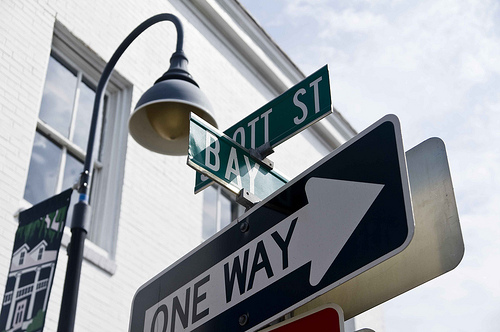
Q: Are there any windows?
A: Yes, there is a window.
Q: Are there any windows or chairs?
A: Yes, there is a window.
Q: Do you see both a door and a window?
A: No, there is a window but no doors.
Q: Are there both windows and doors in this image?
A: No, there is a window but no doors.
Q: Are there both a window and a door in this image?
A: No, there is a window but no doors.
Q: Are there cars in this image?
A: No, there are no cars.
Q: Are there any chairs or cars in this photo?
A: No, there are no cars or chairs.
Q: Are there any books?
A: No, there are no books.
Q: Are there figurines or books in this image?
A: No, there are no books or figurines.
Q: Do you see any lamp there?
A: Yes, there is a lamp.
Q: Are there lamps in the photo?
A: Yes, there is a lamp.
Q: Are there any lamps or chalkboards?
A: Yes, there is a lamp.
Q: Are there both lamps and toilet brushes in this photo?
A: No, there is a lamp but no toilet brushes.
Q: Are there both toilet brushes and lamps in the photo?
A: No, there is a lamp but no toilet brushes.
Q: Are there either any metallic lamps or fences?
A: Yes, there is a metal lamp.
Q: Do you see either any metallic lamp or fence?
A: Yes, there is a metal lamp.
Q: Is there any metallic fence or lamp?
A: Yes, there is a metal lamp.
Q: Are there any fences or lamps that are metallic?
A: Yes, the lamp is metallic.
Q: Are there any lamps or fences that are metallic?
A: Yes, the lamp is metallic.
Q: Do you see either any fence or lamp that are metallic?
A: Yes, the lamp is metallic.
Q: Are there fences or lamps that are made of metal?
A: Yes, the lamp is made of metal.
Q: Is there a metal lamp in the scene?
A: Yes, there is a metal lamp.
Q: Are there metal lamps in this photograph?
A: Yes, there is a metal lamp.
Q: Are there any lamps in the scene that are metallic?
A: Yes, there is a lamp that is metallic.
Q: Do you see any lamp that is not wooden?
A: Yes, there is a metallic lamp.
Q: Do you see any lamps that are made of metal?
A: Yes, there is a lamp that is made of metal.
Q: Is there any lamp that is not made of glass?
A: Yes, there is a lamp that is made of metal.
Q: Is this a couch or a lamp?
A: This is a lamp.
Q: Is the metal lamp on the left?
A: Yes, the lamp is on the left of the image.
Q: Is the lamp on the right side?
A: No, the lamp is on the left of the image.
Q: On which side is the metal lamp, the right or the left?
A: The lamp is on the left of the image.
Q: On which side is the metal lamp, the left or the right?
A: The lamp is on the left of the image.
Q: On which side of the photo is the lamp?
A: The lamp is on the left of the image.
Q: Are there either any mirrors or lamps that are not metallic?
A: No, there is a lamp but it is metallic.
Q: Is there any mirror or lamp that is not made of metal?
A: No, there is a lamp but it is made of metal.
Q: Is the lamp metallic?
A: Yes, the lamp is metallic.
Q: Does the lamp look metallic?
A: Yes, the lamp is metallic.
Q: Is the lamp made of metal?
A: Yes, the lamp is made of metal.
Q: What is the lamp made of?
A: The lamp is made of metal.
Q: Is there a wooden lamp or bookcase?
A: No, there is a lamp but it is metallic.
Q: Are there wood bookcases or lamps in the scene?
A: No, there is a lamp but it is metallic.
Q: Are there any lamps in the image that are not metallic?
A: No, there is a lamp but it is metallic.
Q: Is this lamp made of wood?
A: No, the lamp is made of metal.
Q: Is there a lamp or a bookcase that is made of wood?
A: No, there is a lamp but it is made of metal.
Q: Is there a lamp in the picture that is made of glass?
A: No, there is a lamp but it is made of metal.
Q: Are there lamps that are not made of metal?
A: No, there is a lamp but it is made of metal.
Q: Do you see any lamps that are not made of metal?
A: No, there is a lamp but it is made of metal.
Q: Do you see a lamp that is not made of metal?
A: No, there is a lamp but it is made of metal.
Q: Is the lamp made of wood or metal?
A: The lamp is made of metal.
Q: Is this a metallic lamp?
A: Yes, this is a metallic lamp.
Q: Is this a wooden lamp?
A: No, this is a metallic lamp.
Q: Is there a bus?
A: No, there are no buses.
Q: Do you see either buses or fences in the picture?
A: No, there are no buses or fences.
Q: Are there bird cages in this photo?
A: No, there are no bird cages.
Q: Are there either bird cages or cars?
A: No, there are no bird cages or cars.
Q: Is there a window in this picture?
A: Yes, there is a window.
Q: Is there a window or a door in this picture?
A: Yes, there is a window.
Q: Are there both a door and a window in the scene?
A: No, there is a window but no doors.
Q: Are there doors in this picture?
A: No, there are no doors.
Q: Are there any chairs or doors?
A: No, there are no doors or chairs.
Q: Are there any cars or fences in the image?
A: No, there are no cars or fences.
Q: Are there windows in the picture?
A: Yes, there is a window.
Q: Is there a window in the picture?
A: Yes, there is a window.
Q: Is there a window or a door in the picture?
A: Yes, there is a window.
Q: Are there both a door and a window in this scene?
A: No, there is a window but no doors.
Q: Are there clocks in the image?
A: No, there are no clocks.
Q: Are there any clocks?
A: No, there are no clocks.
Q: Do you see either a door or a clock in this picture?
A: No, there are no clocks or doors.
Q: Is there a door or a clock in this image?
A: No, there are no clocks or doors.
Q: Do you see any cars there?
A: No, there are no cars.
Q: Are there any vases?
A: No, there are no vases.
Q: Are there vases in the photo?
A: No, there are no vases.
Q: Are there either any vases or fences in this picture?
A: No, there are no vases or fences.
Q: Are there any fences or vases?
A: No, there are no vases or fences.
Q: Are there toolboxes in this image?
A: No, there are no toolboxes.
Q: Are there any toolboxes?
A: No, there are no toolboxes.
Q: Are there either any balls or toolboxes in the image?
A: No, there are no toolboxes or balls.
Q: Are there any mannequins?
A: No, there are no mannequins.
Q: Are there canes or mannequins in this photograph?
A: No, there are no mannequins or canes.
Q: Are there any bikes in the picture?
A: No, there are no bikes.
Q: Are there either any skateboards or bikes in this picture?
A: No, there are no bikes or skateboards.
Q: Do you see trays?
A: No, there are no trays.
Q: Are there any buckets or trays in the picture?
A: No, there are no trays or buckets.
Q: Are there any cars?
A: No, there are no cars.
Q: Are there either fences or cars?
A: No, there are no cars or fences.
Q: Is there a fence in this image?
A: No, there are no fences.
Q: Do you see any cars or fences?
A: No, there are no fences or cars.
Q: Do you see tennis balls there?
A: No, there are no tennis balls.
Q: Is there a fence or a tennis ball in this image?
A: No, there are no tennis balls or fences.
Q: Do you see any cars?
A: No, there are no cars.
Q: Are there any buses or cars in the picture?
A: No, there are no cars or buses.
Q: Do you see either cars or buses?
A: No, there are no cars or buses.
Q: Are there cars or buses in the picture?
A: No, there are no cars or buses.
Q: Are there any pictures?
A: No, there are no pictures.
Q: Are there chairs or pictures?
A: No, there are no pictures or chairs.